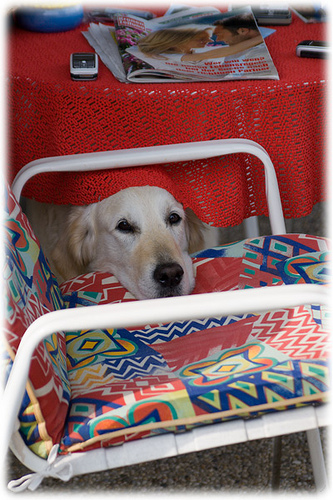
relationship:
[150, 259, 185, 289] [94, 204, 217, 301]
nose of dog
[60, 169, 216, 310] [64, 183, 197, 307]
dog has a head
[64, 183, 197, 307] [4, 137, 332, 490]
head on a chair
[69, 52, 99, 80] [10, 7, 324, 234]
phone on a table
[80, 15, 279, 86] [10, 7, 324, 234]
magazines on a table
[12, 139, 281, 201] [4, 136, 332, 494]
arm on a chair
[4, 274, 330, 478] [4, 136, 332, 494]
arm on a chair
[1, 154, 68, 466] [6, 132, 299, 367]
cushion on a chair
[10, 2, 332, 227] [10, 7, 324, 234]
table cloth on a table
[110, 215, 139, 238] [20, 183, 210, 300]
eye on a dog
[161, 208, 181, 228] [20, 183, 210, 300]
eye on a dog